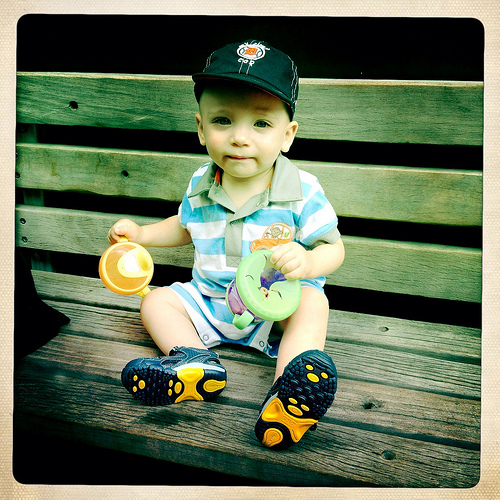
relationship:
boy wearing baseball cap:
[105, 41, 340, 447] [192, 39, 299, 121]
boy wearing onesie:
[105, 41, 340, 447] [167, 150, 340, 359]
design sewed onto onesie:
[249, 220, 294, 254] [167, 150, 340, 359]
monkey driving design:
[264, 224, 283, 238] [250, 223, 295, 253]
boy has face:
[105, 41, 340, 447] [202, 86, 285, 177]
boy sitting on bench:
[105, 41, 340, 447] [17, 64, 464, 486]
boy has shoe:
[105, 41, 340, 447] [122, 343, 227, 405]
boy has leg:
[105, 41, 340, 447] [138, 281, 207, 357]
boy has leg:
[105, 41, 340, 447] [273, 282, 332, 386]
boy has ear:
[105, 41, 340, 447] [279, 121, 300, 154]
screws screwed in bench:
[18, 216, 26, 226] [17, 64, 464, 486]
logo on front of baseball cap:
[235, 42, 271, 67] [192, 39, 299, 121]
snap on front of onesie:
[202, 332, 211, 342] [167, 150, 340, 359]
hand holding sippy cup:
[106, 217, 143, 244] [97, 236, 154, 297]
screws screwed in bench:
[21, 235, 29, 244] [17, 64, 464, 486]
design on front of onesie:
[249, 220, 294, 254] [167, 150, 340, 359]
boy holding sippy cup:
[105, 41, 340, 447] [97, 236, 154, 297]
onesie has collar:
[167, 150, 340, 359] [187, 153, 303, 204]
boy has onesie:
[105, 41, 340, 447] [167, 150, 340, 359]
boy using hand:
[105, 41, 340, 447] [106, 217, 143, 244]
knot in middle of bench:
[362, 397, 385, 411] [17, 64, 464, 486]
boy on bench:
[105, 41, 340, 447] [17, 64, 464, 486]